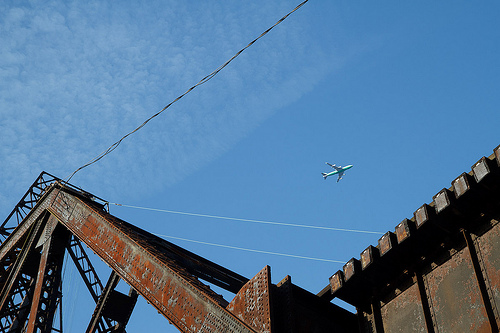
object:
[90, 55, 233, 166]
cable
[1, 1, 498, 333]
blue sky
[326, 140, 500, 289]
roof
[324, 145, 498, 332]
building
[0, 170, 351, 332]
metal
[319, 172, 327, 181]
tail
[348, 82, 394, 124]
ground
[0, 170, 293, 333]
beam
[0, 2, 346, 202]
helmet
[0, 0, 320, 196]
white clouds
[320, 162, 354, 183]
airplane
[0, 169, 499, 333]
bridge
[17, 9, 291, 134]
clouds